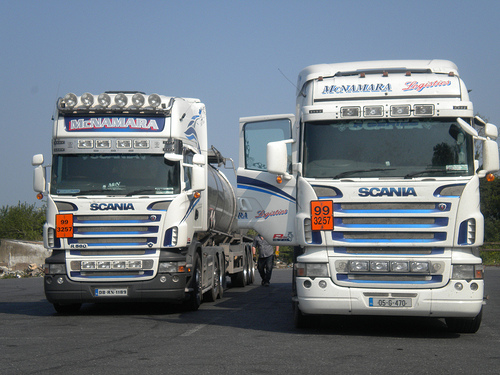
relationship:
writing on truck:
[390, 69, 448, 93] [279, 51, 484, 342]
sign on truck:
[311, 198, 333, 228] [239, 58, 500, 332]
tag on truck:
[365, 289, 417, 311] [250, 44, 484, 344]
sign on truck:
[304, 195, 339, 237] [239, 58, 500, 332]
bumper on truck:
[291, 255, 485, 317] [239, 58, 500, 332]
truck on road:
[239, 58, 500, 332] [1, 257, 496, 367]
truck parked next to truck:
[30, 89, 256, 320] [239, 58, 500, 332]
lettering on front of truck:
[357, 183, 417, 195] [258, 50, 496, 347]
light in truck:
[342, 106, 362, 119] [239, 58, 500, 332]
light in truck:
[364, 102, 385, 117] [239, 58, 500, 332]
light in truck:
[391, 101, 411, 116] [239, 58, 500, 332]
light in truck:
[414, 100, 434, 115] [239, 58, 500, 332]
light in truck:
[64, 91, 78, 108] [30, 89, 256, 320]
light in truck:
[82, 91, 93, 108] [30, 89, 256, 320]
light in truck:
[97, 90, 110, 108] [30, 89, 256, 320]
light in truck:
[129, 90, 145, 110] [30, 89, 256, 320]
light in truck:
[146, 91, 160, 111] [30, 89, 256, 320]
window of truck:
[302, 122, 471, 165] [239, 58, 500, 332]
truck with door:
[239, 60, 498, 309] [237, 111, 301, 245]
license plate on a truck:
[366, 295, 413, 307] [239, 58, 500, 332]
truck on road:
[30, 89, 256, 320] [10, 320, 498, 366]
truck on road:
[239, 58, 500, 332] [10, 320, 498, 366]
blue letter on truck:
[107, 200, 115, 212] [30, 89, 256, 320]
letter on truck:
[125, 202, 135, 210] [30, 89, 256, 320]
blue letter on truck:
[357, 186, 369, 197] [239, 58, 500, 332]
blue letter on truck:
[368, 186, 380, 197] [239, 58, 500, 332]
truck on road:
[30, 89, 256, 320] [9, 313, 494, 373]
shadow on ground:
[138, 282, 300, 332] [0, 262, 494, 374]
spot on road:
[390, 344, 410, 354] [1, 257, 496, 367]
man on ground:
[247, 240, 282, 290] [2, 271, 498, 372]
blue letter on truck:
[405, 187, 415, 197] [239, 58, 500, 332]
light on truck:
[64, 91, 78, 108] [39, 89, 254, 298]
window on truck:
[47, 154, 184, 208] [38, 80, 256, 335]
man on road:
[247, 222, 281, 284] [198, 237, 295, 373]